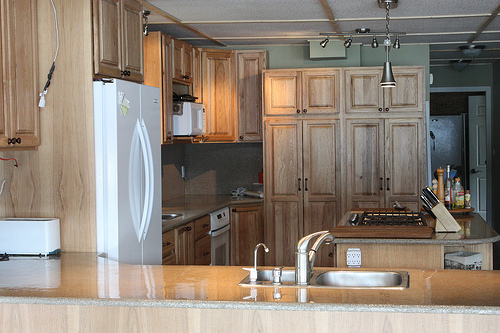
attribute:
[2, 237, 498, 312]
counter — shiny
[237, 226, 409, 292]
sink — pictured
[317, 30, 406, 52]
lights — silver track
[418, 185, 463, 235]
knives — rack, kitchen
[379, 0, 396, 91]
light — kitchen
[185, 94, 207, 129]
microwave — oven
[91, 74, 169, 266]
fridge — white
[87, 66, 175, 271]
refrigerator — white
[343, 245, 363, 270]
outlets — electrical 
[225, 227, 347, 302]
taps — pictured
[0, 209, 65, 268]
toasting machine — toaster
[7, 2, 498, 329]
scene — inside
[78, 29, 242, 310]
refrigerator — white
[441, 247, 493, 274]
can — trash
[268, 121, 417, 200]
cupboards — tan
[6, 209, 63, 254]
toaster — white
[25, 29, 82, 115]
cord — electrical 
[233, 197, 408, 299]
faucet — silver 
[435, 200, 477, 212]
tray — wooden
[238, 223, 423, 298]
sink — silver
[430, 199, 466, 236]
knifeblock — wooden